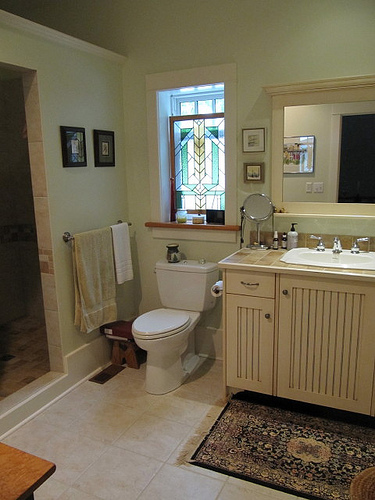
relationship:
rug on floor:
[184, 392, 372, 498] [98, 380, 149, 398]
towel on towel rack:
[71, 228, 119, 328] [62, 229, 75, 248]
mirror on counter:
[241, 192, 279, 255] [214, 229, 373, 283]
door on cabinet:
[263, 269, 374, 420] [212, 232, 374, 428]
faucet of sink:
[310, 234, 368, 253] [280, 245, 374, 268]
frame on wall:
[60, 127, 88, 169] [2, 23, 124, 381]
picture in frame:
[59, 126, 87, 167] [60, 127, 88, 169]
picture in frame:
[66, 130, 83, 159] [93, 130, 116, 168]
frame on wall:
[93, 130, 116, 168] [2, 23, 124, 381]